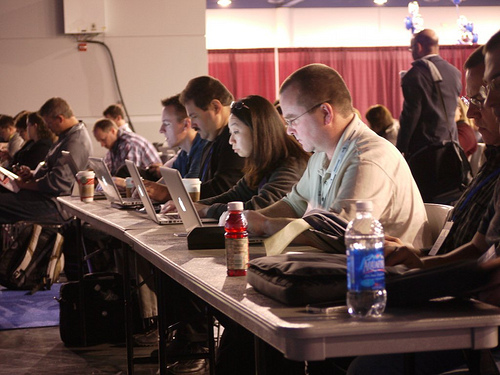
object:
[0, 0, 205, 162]
wall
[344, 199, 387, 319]
bottle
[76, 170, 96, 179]
lid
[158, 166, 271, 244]
laptop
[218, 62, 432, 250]
person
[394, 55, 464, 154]
coat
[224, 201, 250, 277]
bottle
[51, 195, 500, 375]
table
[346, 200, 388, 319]
aquafina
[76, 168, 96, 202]
cup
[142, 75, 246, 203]
man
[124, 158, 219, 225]
laptop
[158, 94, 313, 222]
woman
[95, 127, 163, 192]
shirt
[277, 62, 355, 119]
hair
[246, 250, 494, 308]
bag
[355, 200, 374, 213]
lid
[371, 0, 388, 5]
light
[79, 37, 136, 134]
cable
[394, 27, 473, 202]
guy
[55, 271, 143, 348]
bag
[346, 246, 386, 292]
label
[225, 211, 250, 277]
liquid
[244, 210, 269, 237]
hand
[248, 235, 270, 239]
keyboard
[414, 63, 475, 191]
bag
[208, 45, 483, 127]
curtain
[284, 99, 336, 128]
glasses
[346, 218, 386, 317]
water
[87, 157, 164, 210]
laptop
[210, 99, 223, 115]
left ear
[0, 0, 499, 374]
room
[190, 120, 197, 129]
nose